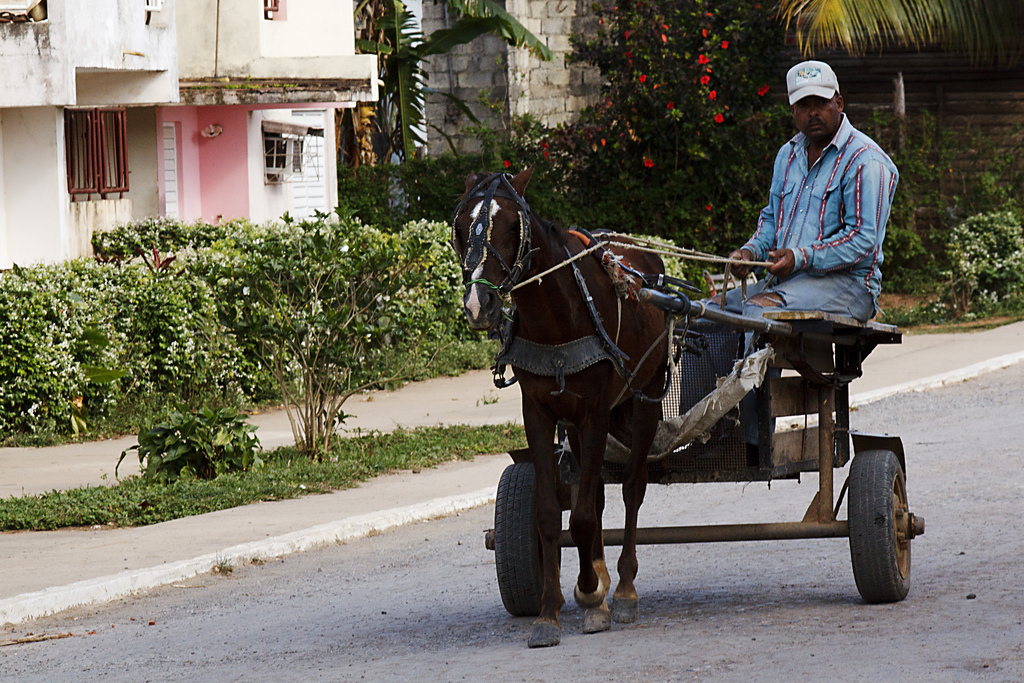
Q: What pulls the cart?
A: A horse.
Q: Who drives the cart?
A: A man.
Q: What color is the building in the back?
A: Pink.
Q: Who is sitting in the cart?
A: Man in a white hat.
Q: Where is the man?
A: Sitting in the cart.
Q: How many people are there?
A: 1.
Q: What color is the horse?
A: Brown.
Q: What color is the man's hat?
A: White.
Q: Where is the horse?
A: Attached to the cart.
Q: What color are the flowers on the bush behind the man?
A: Red.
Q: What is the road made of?
A: Asphalt.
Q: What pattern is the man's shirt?
A: Striped.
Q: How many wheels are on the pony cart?
A: Two.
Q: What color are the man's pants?
A: Blue.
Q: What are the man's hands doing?
A: Holding the reins.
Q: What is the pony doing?
A: Pulling the cart.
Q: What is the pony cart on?
A: Road.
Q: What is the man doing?
A: Driving the carriage.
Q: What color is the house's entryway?
A: Pink.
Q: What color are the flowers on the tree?
A: Red.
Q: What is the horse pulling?
A: A wagon and a man.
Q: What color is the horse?
A: Brown.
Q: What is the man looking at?
A: The person taking the picture.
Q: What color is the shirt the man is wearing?
A: Blue and red.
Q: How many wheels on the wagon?
A: Two.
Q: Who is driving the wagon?
A: A man.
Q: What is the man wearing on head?
A: A baseball hat.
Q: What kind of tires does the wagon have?
A: Rubber.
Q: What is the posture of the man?
A: Sitting down.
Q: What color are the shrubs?
A: Green.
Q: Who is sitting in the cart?
A: Man with white hat.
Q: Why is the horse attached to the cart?
A: Pulling it.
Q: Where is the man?
A: In the cart.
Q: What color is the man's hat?
A: White.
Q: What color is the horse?
A: Brown.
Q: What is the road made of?
A: Asphalt.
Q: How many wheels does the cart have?
A: 2.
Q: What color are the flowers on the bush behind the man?
A: Red.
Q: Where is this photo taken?
A: On a road.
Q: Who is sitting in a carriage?
A: A man.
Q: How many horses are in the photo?
A: One.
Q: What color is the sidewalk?
A: White.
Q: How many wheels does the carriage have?
A: Two.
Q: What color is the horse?
A: Brown.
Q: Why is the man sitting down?
A: Because the carriage is moving and he doesn't want to fall.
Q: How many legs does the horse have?
A: Four.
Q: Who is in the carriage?
A: A man.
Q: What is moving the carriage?
A: A horse.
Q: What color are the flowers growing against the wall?
A: Red.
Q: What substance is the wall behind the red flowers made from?
A: Stone.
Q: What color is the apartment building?
A: White.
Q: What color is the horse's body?
A: Brown.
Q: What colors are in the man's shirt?
A: Blue, red and white.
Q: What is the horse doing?
A: Pulling a cart.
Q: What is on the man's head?
A: Baseball cap.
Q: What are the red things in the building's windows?
A: Metal bars.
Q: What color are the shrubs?
A: Green.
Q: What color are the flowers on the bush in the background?
A: Red.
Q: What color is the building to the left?
A: Pink.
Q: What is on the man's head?
A: A hat.